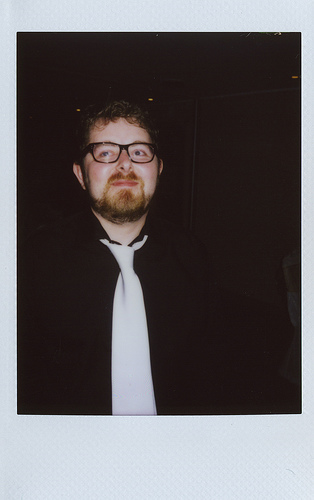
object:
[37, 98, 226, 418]
man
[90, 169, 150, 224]
beard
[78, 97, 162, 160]
hair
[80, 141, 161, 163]
glasses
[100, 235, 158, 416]
tie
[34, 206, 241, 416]
shirt